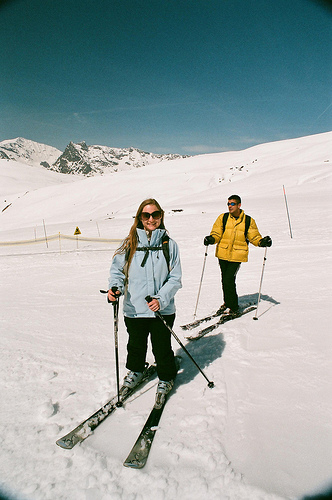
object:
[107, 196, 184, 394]
person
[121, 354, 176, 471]
skis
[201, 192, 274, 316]
person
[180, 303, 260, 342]
skis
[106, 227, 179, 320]
jacket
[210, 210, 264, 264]
jacket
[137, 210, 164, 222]
sunglasses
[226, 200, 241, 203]
sunglasses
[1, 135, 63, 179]
mountains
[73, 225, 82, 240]
sign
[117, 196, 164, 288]
hair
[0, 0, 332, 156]
sky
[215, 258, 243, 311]
pants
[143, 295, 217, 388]
ski pole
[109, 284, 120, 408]
ski pole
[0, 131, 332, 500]
snow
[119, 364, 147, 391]
boot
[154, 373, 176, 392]
boot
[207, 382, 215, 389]
tip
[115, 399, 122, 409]
tip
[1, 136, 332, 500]
area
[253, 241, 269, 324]
ski pole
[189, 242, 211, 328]
ski pole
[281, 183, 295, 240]
pole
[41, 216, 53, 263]
pole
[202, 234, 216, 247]
glove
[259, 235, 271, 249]
glove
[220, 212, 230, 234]
strap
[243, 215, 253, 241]
strap